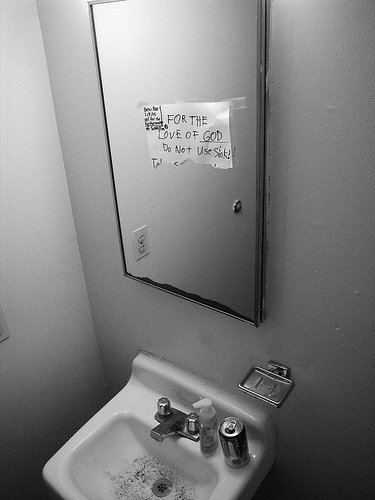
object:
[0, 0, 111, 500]
wall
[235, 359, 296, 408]
soap dish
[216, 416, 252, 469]
can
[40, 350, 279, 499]
sink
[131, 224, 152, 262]
socket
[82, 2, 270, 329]
mirror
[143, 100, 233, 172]
note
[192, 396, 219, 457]
soap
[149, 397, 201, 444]
faucet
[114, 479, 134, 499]
debris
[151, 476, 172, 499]
drain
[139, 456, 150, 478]
black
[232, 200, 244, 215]
stopper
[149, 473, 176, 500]
bottom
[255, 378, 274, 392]
metal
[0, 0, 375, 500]
bathroom